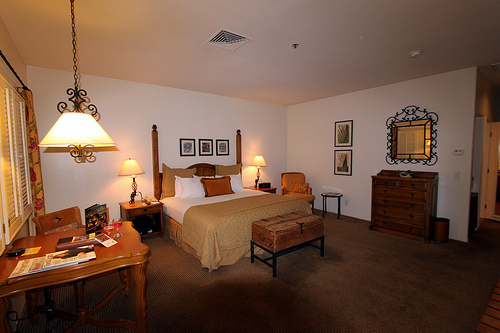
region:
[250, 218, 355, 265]
chest in front of bed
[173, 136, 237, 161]
three frames above headboard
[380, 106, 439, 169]
beautiful mirror above dresser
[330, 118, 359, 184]
two frames hung vertically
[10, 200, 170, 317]
wooden table against window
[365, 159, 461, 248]
all wood distressed dresser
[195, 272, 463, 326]
hard wood floors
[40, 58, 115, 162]
ceiling lamp hanging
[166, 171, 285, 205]
clean made up bed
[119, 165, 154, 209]
nightstand lamp on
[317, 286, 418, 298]
the rug is brown in color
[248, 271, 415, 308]
the rug is on the floor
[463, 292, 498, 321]
the floor is made of wood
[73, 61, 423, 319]
it is an indoor scene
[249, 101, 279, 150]
the wall is white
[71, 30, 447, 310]
this is a bedroom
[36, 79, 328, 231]
the lights are on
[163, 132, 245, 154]
there are pictures on the wall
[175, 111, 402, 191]
the pictures are framed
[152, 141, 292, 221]
pillows are on the bed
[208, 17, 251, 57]
Air vent on ceiling.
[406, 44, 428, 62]
Smoke alarm on ceiling.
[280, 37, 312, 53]
Water spout on ceiling.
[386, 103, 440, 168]
Mirror above wooden dresser.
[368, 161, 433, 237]
Wooden dresser below mirror on wall.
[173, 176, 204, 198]
White pillow on the left side of the brown pillow on bed.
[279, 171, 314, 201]
Brown chair next to the right side of the bed.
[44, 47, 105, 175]
Hanging lamp above wooden table on left side of room.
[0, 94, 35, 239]
White wooden window shades.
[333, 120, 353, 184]
Two picture frames on the wall.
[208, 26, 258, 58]
A ceiling vent for air and heat.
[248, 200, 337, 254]
A unique truck bench at the end of the bed.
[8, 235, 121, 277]
Several magazines sitting on a table.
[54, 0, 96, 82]
A chain holding up a lamp.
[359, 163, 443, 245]
A brown chest of drawers.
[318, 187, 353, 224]
A small table by the wall.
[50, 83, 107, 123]
Metal decorative design on hanging lamp.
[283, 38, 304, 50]
A sprinkling system in ceiling.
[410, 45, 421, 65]
A smoke alarm in ceiling.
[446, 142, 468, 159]
A thermastat.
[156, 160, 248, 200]
Pillows on the bed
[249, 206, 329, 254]
Wooden locker at the foot of the bed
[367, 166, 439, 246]
Wood dresser against the wall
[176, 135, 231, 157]
Pictures hanging above the bed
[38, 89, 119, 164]
Lamp hanging above the table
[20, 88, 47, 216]
Curtains for the window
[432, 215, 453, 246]
Brown waste basket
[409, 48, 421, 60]
Ceiling mounted smoke detector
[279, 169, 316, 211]
Chair in the corner of the room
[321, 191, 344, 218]
Small table next to the chair